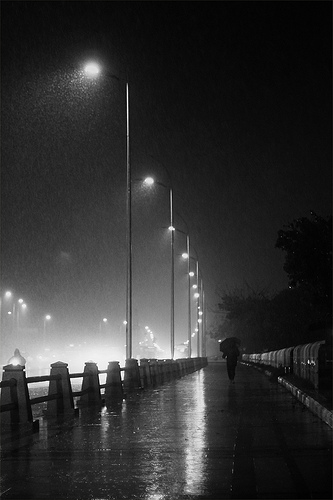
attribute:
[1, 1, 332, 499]
photo — nighttime, black, white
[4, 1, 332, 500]
nighttime — raining, rainy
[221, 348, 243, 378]
person — walking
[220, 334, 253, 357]
umbrella — sheltering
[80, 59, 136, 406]
streelamp — activated, active, bright, shining down, on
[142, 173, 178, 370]
streelamp — activated, active, bright, shining down, on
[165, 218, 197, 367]
streelamp — on, activated, active, bright, shining down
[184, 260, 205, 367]
streelamp — on, activated, active, bright, shining down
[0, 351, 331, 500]
sidewalk — wide, wet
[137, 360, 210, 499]
light — reflecting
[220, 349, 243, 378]
coat — dark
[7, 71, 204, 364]
mist — white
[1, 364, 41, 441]
column — stone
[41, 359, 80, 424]
column — stone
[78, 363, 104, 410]
column — stone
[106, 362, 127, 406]
column — stone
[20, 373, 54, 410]
pole — metal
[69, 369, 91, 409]
pole — metal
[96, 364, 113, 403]
pole — metal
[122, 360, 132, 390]
pole — metal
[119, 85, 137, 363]
metal pole — tall, grey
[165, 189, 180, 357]
metal pole — tall, grey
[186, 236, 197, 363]
metal pole — tall, grey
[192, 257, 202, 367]
metal pole — tall, grey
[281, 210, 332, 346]
tree — hanging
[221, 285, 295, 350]
tree — hanging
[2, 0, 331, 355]
sky — black, rainy